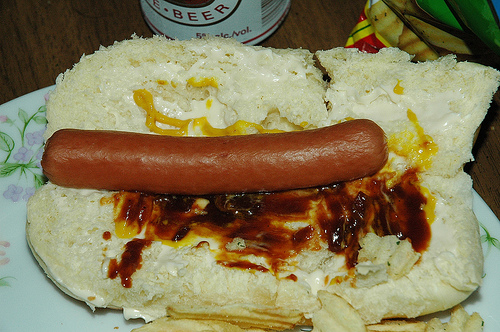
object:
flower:
[13, 147, 32, 161]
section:
[325, 119, 388, 185]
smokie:
[143, 157, 175, 170]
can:
[140, 0, 291, 46]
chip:
[358, 230, 419, 287]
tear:
[312, 52, 334, 113]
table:
[0, 0, 499, 218]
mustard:
[130, 88, 438, 172]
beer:
[173, 4, 230, 22]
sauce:
[104, 168, 433, 289]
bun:
[28, 37, 499, 317]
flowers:
[4, 185, 23, 203]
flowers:
[25, 132, 41, 146]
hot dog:
[40, 118, 388, 195]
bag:
[345, 0, 500, 64]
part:
[208, 0, 289, 46]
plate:
[0, 83, 499, 332]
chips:
[314, 291, 367, 331]